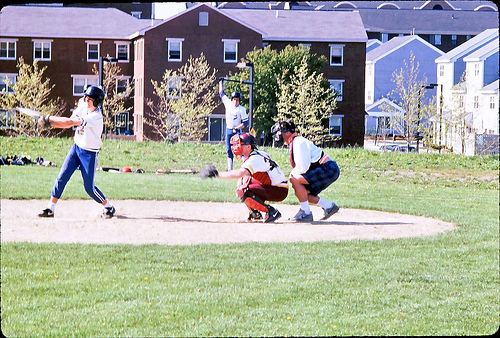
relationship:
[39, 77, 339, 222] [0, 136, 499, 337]
kids playing on field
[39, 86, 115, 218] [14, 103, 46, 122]
kid swinging bat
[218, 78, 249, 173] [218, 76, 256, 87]
kid holding bat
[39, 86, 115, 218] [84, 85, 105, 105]
kid wearing helmet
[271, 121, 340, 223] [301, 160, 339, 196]
umpire wearing shorts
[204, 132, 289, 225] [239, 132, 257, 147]
catcher wearing helmet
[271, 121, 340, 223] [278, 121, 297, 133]
umpire wearing helmet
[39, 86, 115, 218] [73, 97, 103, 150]
kid wearing shirt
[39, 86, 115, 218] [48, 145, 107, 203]
kid wearing pants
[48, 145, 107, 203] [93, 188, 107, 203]
pants have stripes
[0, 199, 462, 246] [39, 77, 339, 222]
sand under kids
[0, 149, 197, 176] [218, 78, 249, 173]
supplies by kid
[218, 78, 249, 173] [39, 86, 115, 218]
kid behind kid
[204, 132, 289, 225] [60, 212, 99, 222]
catcher behind plate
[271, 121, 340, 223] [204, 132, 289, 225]
umpire behind catcher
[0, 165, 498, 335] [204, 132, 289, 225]
grass next to catcher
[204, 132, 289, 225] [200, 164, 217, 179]
catcher has glove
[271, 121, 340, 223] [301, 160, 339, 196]
umpire has shorts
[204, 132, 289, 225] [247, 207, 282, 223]
catcher has shoes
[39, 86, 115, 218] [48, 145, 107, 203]
kid has pants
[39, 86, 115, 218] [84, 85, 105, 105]
kid has helmet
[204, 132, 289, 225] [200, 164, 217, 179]
catcher wearing glove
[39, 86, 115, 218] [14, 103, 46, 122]
kid holding bat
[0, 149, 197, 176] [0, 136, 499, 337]
supplies in field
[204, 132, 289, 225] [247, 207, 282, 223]
catcher wearing shoes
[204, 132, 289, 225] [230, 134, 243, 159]
catcher has mask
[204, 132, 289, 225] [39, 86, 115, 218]
catcher squatting behind kid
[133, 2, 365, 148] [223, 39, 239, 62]
building has window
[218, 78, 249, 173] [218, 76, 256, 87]
kid swinging bat